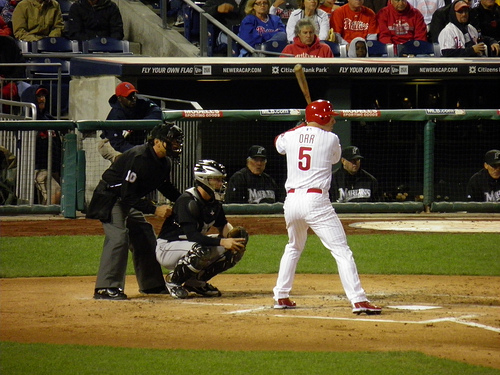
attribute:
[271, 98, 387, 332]
baseball player — batting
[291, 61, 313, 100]
bat — wooden, brown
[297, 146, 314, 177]
number — red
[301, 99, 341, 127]
helmet — red, shiny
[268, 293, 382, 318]
shoes — red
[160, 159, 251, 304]
catcher — squatting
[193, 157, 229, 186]
helmet — silver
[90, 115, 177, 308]
umpire — standing, waiting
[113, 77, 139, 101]
hat — red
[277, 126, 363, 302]
uniform — white, red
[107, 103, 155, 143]
sweatshirt — blue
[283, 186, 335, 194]
belt — red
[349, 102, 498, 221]
railing — green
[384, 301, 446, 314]
home plate — white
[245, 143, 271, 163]
baseball cap — black, white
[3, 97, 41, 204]
fence — metal